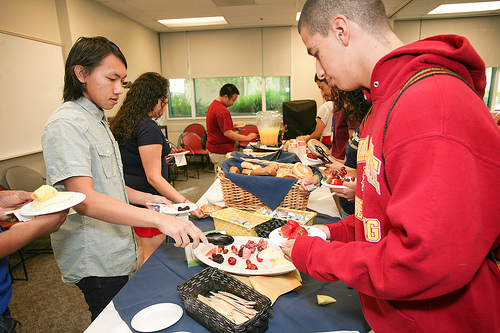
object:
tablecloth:
[83, 176, 374, 332]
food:
[204, 156, 359, 273]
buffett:
[162, 157, 358, 277]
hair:
[108, 71, 165, 146]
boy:
[39, 35, 208, 323]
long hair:
[60, 35, 126, 103]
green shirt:
[39, 95, 140, 286]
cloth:
[229, 272, 303, 307]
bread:
[228, 161, 314, 179]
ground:
[0, 268, 88, 333]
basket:
[216, 156, 311, 212]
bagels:
[229, 162, 314, 179]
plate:
[268, 224, 327, 248]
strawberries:
[206, 237, 265, 272]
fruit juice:
[256, 128, 277, 146]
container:
[255, 110, 283, 145]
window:
[165, 73, 291, 120]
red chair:
[176, 132, 210, 180]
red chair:
[183, 123, 206, 140]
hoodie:
[291, 34, 500, 333]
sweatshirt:
[311, 55, 482, 328]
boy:
[279, 0, 500, 331]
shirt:
[205, 99, 236, 154]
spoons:
[194, 289, 260, 327]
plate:
[193, 236, 298, 277]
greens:
[169, 91, 290, 117]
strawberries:
[280, 219, 308, 240]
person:
[111, 72, 212, 222]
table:
[82, 143, 369, 333]